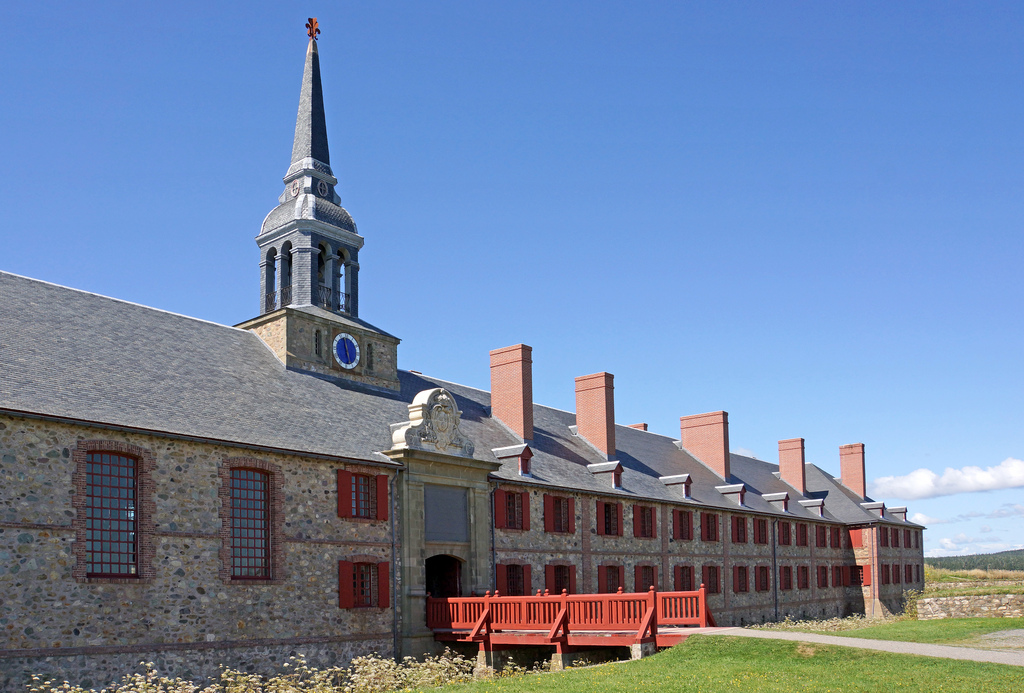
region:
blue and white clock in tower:
[325, 314, 377, 381]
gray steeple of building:
[246, 20, 389, 319]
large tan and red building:
[13, 337, 959, 686]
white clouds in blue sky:
[50, 125, 128, 174]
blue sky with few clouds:
[2, 1, 1021, 558]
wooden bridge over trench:
[428, 582, 707, 674]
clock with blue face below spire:
[332, 328, 362, 367]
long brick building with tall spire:
[0, 18, 930, 685]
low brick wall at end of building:
[908, 589, 1022, 616]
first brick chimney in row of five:
[491, 344, 533, 436]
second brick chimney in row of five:
[570, 369, 618, 455]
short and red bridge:
[420, 588, 715, 674]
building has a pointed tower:
[0, 0, 934, 690]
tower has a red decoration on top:
[239, 10, 405, 388]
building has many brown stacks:
[3, 12, 927, 690]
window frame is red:
[338, 468, 393, 522]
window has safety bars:
[75, 439, 151, 583]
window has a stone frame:
[214, 452, 285, 589]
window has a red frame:
[337, 556, 395, 613]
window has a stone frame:
[72, 440, 152, 586]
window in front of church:
[505, 487, 521, 527]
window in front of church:
[505, 564, 523, 595]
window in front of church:
[551, 493, 569, 531]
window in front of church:
[552, 564, 572, 595]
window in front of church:
[604, 502, 618, 534]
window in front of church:
[607, 562, 621, 591]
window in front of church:
[638, 504, 654, 536]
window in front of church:
[638, 562, 659, 591]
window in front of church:
[675, 507, 693, 539]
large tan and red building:
[11, 17, 945, 647]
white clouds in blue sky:
[727, 161, 820, 260]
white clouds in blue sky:
[561, 121, 622, 186]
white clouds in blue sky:
[803, 74, 934, 231]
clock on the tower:
[328, 325, 364, 365]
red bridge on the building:
[414, 556, 705, 648]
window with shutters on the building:
[704, 506, 724, 542]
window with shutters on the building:
[324, 463, 394, 522]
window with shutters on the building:
[323, 551, 397, 612]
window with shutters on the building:
[492, 479, 528, 543]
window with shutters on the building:
[485, 548, 534, 594]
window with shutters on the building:
[535, 488, 580, 542]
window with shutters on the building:
[545, 555, 575, 601]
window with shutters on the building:
[587, 493, 632, 542]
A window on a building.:
[65, 447, 154, 597]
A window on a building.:
[214, 465, 295, 593]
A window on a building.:
[345, 468, 375, 520]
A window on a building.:
[348, 558, 372, 597]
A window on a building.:
[337, 468, 401, 516]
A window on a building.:
[344, 557, 398, 605]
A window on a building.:
[495, 494, 540, 530]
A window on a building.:
[543, 492, 576, 532]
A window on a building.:
[599, 495, 619, 534]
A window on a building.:
[635, 504, 659, 537]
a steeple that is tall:
[245, 31, 373, 200]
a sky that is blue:
[435, 66, 818, 285]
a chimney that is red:
[468, 344, 576, 440]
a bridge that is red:
[450, 581, 695, 671]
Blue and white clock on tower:
[327, 323, 369, 374]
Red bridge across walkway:
[416, 583, 715, 660]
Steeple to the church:
[265, 14, 373, 318]